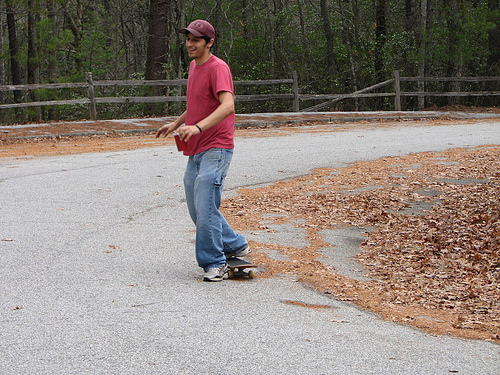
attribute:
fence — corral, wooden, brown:
[0, 68, 499, 120]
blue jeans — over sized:
[181, 146, 248, 271]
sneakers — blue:
[187, 240, 272, 291]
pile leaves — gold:
[343, 194, 498, 322]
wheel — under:
[245, 268, 256, 280]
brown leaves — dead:
[352, 179, 499, 276]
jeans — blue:
[184, 141, 242, 256]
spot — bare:
[332, 234, 357, 267]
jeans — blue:
[182, 145, 247, 271]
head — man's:
[184, 18, 217, 58]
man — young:
[154, 18, 252, 282]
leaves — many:
[242, 143, 497, 319]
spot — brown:
[280, 292, 339, 319]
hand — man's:
[176, 120, 201, 145]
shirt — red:
[179, 57, 235, 153]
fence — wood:
[0, 79, 178, 109]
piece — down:
[305, 67, 395, 111]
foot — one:
[230, 240, 250, 258]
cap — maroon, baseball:
[179, 15, 219, 44]